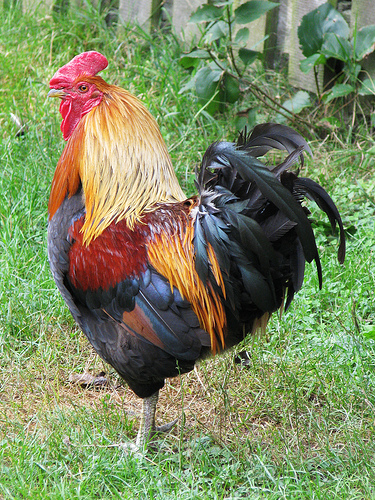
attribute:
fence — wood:
[5, 2, 373, 114]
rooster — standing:
[44, 49, 345, 466]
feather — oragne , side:
[145, 218, 228, 352]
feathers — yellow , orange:
[71, 102, 181, 230]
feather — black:
[192, 139, 324, 291]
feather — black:
[232, 122, 311, 164]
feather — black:
[203, 185, 274, 269]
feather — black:
[199, 207, 233, 275]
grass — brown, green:
[6, 71, 358, 486]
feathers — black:
[196, 113, 358, 305]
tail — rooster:
[181, 113, 355, 334]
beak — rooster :
[46, 84, 72, 104]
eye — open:
[71, 80, 95, 103]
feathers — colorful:
[41, 72, 338, 388]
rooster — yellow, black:
[31, 35, 357, 481]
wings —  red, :
[68, 206, 234, 365]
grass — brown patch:
[11, 266, 367, 486]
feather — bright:
[198, 138, 321, 283]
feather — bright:
[193, 211, 210, 290]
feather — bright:
[243, 122, 315, 161]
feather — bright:
[237, 259, 274, 313]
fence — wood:
[121, 0, 370, 77]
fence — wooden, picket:
[21, 0, 374, 122]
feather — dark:
[195, 139, 317, 264]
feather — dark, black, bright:
[289, 172, 346, 264]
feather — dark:
[233, 121, 313, 168]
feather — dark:
[244, 143, 303, 218]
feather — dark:
[193, 210, 211, 287]